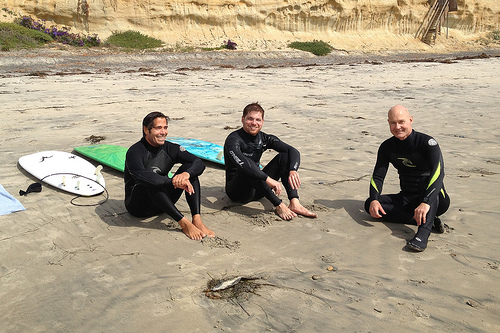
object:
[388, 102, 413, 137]
head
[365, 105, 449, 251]
man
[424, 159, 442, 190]
stripe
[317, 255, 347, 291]
rock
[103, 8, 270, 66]
cliff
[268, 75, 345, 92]
beach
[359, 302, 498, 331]
beach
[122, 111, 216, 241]
man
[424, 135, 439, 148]
decal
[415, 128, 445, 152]
shoulder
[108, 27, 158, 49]
plants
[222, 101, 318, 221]
man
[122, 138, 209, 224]
swim suit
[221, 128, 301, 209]
swim suit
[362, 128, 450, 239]
swim suit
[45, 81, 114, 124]
beach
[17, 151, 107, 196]
board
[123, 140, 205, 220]
suit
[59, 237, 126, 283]
sand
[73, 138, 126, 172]
surf board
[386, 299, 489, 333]
ground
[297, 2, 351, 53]
cliff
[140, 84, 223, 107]
beach